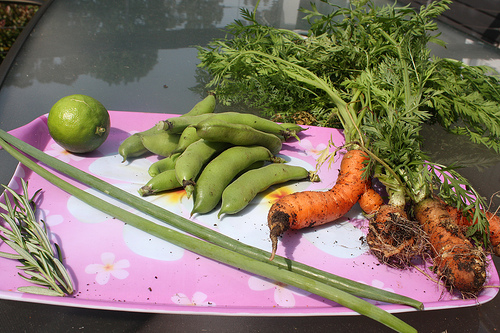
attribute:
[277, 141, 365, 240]
carrot — bright orange, dirty, here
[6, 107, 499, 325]
plate — pink, white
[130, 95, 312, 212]
beans — large, green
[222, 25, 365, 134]
leaves — green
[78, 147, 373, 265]
flower design — yellow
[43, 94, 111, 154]
lime — green, round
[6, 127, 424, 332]
vegetable — skinny, long, green, stalk-like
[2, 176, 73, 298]
herb — green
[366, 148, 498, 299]
vegetables — orange, root